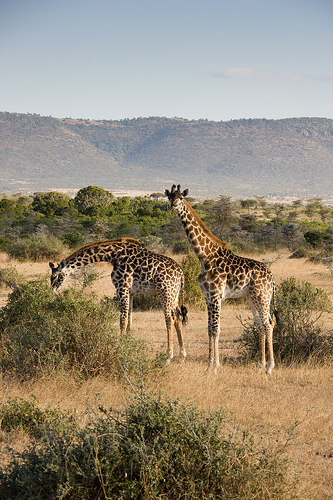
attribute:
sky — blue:
[0, 0, 332, 121]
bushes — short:
[6, 281, 118, 367]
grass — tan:
[1, 182, 332, 498]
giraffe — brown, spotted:
[32, 216, 193, 385]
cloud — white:
[209, 59, 249, 82]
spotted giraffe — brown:
[162, 182, 283, 376]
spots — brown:
[213, 254, 229, 268]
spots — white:
[188, 221, 202, 237]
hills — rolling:
[4, 106, 331, 191]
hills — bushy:
[3, 109, 325, 196]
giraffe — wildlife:
[163, 184, 280, 374]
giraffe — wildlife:
[47, 235, 187, 364]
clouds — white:
[211, 60, 320, 92]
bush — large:
[2, 275, 132, 376]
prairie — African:
[4, 189, 331, 495]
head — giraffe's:
[164, 182, 189, 208]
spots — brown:
[236, 271, 245, 281]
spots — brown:
[133, 265, 142, 274]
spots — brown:
[84, 247, 94, 256]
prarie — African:
[15, 189, 331, 491]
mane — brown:
[175, 194, 232, 248]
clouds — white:
[201, 58, 321, 99]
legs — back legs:
[194, 262, 276, 376]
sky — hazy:
[109, 67, 188, 111]